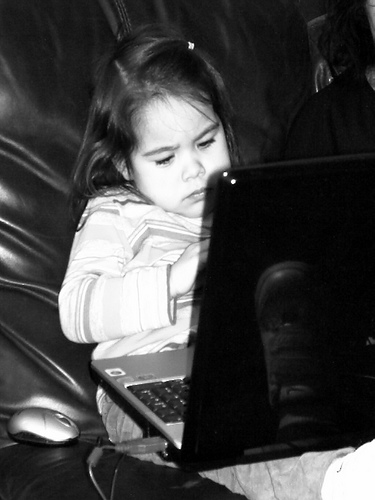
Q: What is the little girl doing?
A: Looking at the laptop.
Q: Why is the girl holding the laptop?
A: She is using it.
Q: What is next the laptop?
A: A mouse.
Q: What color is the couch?
A: Black.